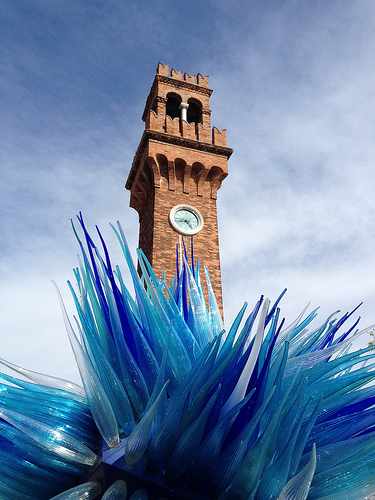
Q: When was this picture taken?
A: During the day.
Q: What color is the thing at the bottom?
A: Blue.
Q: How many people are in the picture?
A: None.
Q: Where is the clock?
A: On the tower.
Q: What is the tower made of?
A: Bricks.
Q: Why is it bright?
A: Its day time.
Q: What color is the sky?
A: Blue.